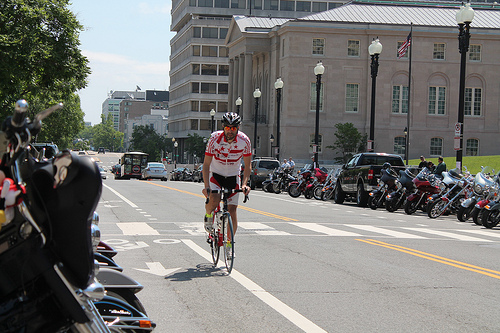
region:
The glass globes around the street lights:
[455, 6, 476, 23]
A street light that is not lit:
[455, 9, 475, 164]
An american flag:
[401, 22, 413, 164]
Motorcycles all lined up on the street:
[372, 165, 496, 222]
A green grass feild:
[411, 153, 498, 175]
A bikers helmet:
[222, 109, 240, 123]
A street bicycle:
[205, 186, 246, 273]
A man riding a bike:
[198, 123, 245, 243]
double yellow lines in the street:
[357, 235, 497, 325]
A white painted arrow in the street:
[134, 255, 182, 277]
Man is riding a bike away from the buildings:
[199, 110, 256, 283]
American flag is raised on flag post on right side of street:
[390, 28, 422, 58]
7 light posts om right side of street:
[196, 3, 488, 130]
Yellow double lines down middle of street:
[339, 222, 498, 304]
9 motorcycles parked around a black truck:
[271, 154, 496, 222]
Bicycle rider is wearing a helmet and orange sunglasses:
[218, 115, 248, 141]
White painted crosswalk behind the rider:
[112, 210, 489, 249]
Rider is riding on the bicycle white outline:
[202, 244, 244, 284]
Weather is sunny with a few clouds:
[75, 4, 171, 127]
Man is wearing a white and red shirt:
[199, 135, 259, 196]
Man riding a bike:
[202, 113, 252, 273]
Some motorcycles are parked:
[262, 165, 499, 227]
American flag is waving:
[398, 29, 410, 59]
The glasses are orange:
[224, 122, 239, 133]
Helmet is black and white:
[224, 111, 241, 123]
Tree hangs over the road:
[1, 1, 89, 150]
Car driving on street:
[142, 162, 165, 182]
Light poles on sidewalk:
[172, 2, 472, 177]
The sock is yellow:
[205, 211, 211, 218]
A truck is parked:
[335, 152, 417, 204]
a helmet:
[223, 111, 240, 125]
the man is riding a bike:
[197, 109, 267, 274]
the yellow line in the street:
[418, 243, 469, 274]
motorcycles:
[419, 176, 491, 220]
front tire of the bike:
[230, 236, 237, 259]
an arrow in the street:
[135, 259, 182, 279]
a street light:
[307, 60, 328, 75]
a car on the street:
[135, 158, 167, 178]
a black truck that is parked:
[335, 155, 380, 200]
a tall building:
[165, 9, 201, 126]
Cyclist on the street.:
[197, 108, 260, 277]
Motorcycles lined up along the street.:
[2, 91, 497, 331]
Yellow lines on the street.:
[145, 175, 498, 283]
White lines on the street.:
[96, 155, 497, 332]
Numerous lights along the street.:
[162, 5, 480, 180]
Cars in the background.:
[75, 141, 173, 184]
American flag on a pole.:
[395, 18, 417, 168]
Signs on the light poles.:
[257, 122, 461, 157]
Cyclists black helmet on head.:
[219, 110, 244, 140]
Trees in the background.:
[0, 0, 370, 166]